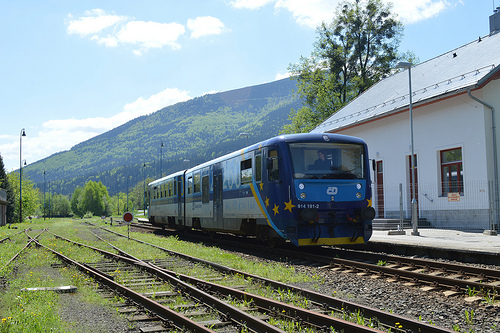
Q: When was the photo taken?
A: Daytime.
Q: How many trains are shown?
A: One.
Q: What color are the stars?
A: Yellow.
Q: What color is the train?
A: Blue.